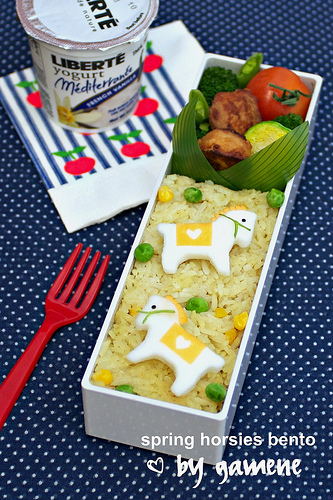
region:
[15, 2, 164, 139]
a pot of yogurt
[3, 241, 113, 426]
a red plastic fork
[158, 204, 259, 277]
a candy shaped like a horse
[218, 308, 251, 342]
corn kernels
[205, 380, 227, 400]
a green pea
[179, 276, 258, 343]
white rice with corn and green peas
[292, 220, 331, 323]
a blue tablecloth with polka white dots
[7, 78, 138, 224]
a colorful paper napkin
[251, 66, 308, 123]
a tomato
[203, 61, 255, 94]
a broccoli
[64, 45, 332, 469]
the plate of food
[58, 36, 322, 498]
the plate is rectangular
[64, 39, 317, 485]
the plate is white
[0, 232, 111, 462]
the fork beside the plate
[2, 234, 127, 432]
the fork is red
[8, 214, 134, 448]
the fork is plastic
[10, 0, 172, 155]
the yogurt on table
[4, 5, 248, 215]
the napkin under the yogurt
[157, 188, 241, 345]
the rice is yellow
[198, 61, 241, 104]
the broccoli in the plate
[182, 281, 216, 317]
a piece of peas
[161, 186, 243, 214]
rice with corn grit and piece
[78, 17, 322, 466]
a rectangular white food container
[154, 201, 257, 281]
a horsey decoration on top of a rice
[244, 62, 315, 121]
a ripe tomato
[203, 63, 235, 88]
a piece of broccoli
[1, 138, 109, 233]
a table napki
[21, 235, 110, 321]
a red fork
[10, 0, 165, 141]
a Liberte yogurt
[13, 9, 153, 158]
a yogurt on top of a napkin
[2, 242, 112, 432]
shiny red plastic fork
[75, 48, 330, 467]
white bento box with food inside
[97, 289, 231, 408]
food in shape of horse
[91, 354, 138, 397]
rice with corn and peas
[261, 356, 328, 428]
blue tablecloth with white polka dots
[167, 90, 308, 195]
meat and vegetables inside leaf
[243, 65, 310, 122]
reddish orange tomato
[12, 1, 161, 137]
French vanilla flavored yogurt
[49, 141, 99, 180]
red fruit on napkin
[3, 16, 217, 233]
napkin with decorative stripes and images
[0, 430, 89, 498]
A blue and white spotted tablecloth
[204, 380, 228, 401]
A green cooked pea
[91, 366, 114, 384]
A piece of yellow corn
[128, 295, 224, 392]
A small horse figure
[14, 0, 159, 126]
A container of vanilla yogurt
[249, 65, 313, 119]
A small tomato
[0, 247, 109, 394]
A red plastic fork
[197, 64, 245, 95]
The top of a piece of broccoli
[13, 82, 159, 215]
A napkin with an apple print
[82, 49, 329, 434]
A bento box filled with food